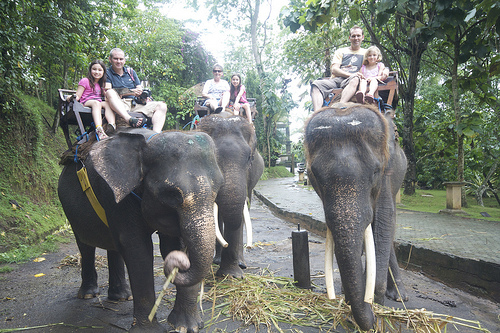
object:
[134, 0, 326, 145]
sky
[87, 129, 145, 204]
ear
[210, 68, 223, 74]
goggles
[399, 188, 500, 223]
grass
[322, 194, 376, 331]
trunk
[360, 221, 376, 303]
tusk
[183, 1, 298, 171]
tree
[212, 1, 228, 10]
leaves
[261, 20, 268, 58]
branches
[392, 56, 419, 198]
trunk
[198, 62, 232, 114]
people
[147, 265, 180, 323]
stick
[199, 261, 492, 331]
straw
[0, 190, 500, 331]
path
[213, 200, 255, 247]
tusks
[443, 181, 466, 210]
garbage can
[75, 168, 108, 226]
strap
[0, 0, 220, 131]
trees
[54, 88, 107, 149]
seat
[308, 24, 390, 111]
man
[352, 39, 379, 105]
daughter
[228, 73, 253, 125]
girl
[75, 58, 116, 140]
girl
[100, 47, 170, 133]
man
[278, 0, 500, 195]
tree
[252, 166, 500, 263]
roadside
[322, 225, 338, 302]
tusk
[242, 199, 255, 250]
tusk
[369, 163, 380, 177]
eye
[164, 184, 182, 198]
eye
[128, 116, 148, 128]
sandal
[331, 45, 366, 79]
shirt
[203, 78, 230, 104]
shirt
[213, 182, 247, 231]
trunk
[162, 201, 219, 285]
trunk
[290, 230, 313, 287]
pole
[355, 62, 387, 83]
shirt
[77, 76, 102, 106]
shirt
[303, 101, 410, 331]
elephant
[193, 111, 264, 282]
elephant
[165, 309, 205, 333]
foot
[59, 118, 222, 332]
elephant